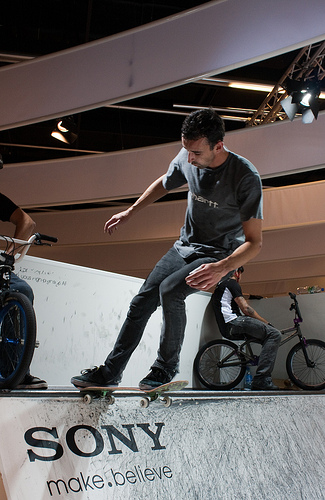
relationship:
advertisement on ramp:
[24, 419, 170, 497] [4, 388, 323, 499]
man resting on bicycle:
[3, 188, 47, 391] [2, 229, 58, 391]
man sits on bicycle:
[211, 267, 284, 391] [192, 293, 323, 389]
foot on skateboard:
[136, 368, 168, 391] [75, 379, 188, 409]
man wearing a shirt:
[71, 111, 265, 386] [161, 143, 262, 263]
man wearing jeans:
[71, 111, 265, 386] [100, 250, 222, 377]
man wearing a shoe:
[71, 111, 265, 386] [137, 366, 166, 390]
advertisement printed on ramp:
[24, 419, 170, 497] [4, 388, 323, 499]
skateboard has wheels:
[75, 379, 188, 409] [81, 391, 171, 408]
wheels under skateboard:
[81, 391, 171, 408] [75, 379, 188, 409]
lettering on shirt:
[188, 190, 219, 211] [161, 143, 262, 263]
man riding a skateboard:
[71, 111, 265, 386] [75, 379, 188, 409]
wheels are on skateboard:
[81, 391, 171, 408] [75, 379, 188, 409]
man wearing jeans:
[211, 267, 284, 391] [226, 315, 283, 379]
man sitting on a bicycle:
[211, 267, 284, 391] [192, 293, 323, 389]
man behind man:
[211, 267, 284, 391] [71, 111, 265, 386]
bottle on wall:
[295, 284, 324, 294] [238, 291, 324, 388]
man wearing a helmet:
[211, 267, 284, 391] [224, 264, 243, 278]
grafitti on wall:
[15, 266, 69, 289] [0, 249, 241, 388]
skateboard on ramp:
[75, 379, 188, 409] [4, 388, 323, 499]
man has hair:
[71, 111, 265, 386] [181, 110, 224, 147]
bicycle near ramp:
[2, 229, 58, 391] [4, 388, 323, 499]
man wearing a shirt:
[211, 267, 284, 391] [215, 276, 242, 328]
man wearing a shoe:
[3, 188, 47, 391] [17, 372, 48, 389]